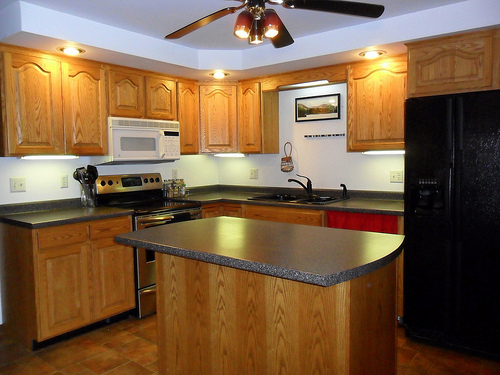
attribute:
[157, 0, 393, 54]
ceiling fan — turn off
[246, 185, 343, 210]
sink — black 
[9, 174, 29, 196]
switch — white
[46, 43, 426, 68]
lamps — three, on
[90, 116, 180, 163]
microwave — white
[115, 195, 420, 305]
counter — kitchen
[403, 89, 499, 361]
refrigerator — black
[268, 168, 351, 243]
faucet — dark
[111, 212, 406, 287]
counter top — gray speckled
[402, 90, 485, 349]
fridge — black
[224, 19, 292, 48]
light — reflected